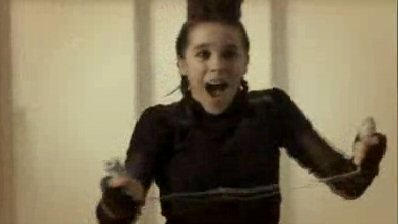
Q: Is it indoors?
A: Yes, it is indoors.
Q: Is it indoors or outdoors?
A: It is indoors.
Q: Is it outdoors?
A: No, it is indoors.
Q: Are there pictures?
A: No, there are no pictures.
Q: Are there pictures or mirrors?
A: No, there are no pictures or mirrors.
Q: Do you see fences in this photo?
A: No, there are no fences.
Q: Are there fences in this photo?
A: No, there are no fences.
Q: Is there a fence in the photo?
A: No, there are no fences.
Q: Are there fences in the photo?
A: No, there are no fences.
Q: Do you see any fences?
A: No, there are no fences.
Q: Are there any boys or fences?
A: No, there are no fences or boys.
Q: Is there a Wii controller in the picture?
A: Yes, there is a Wii controller.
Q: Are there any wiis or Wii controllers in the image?
A: Yes, there is a Wii controller.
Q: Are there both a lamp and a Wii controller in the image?
A: No, there is a Wii controller but no lamps.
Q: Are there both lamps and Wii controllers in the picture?
A: No, there is a Wii controller but no lamps.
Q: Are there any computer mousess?
A: No, there are no computer mousess.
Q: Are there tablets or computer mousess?
A: No, there are no computer mousess or tablets.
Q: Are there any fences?
A: No, there are no fences.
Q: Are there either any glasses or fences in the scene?
A: No, there are no fences or glasses.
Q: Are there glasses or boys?
A: No, there are no boys or glasses.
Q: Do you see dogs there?
A: No, there are no dogs.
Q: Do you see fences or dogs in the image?
A: No, there are no dogs or fences.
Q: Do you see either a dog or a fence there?
A: No, there are no dogs or fences.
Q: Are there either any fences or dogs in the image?
A: No, there are no dogs or fences.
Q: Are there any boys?
A: No, there are no boys.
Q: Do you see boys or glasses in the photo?
A: No, there are no boys or glasses.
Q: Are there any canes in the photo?
A: No, there are no canes.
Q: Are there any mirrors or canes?
A: No, there are no canes or mirrors.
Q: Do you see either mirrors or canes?
A: No, there are no canes or mirrors.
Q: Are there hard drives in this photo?
A: No, there are no hard drives.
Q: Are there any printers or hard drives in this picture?
A: No, there are no hard drives or printers.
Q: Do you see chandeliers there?
A: No, there are no chandeliers.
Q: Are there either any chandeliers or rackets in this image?
A: No, there are no chandeliers or rackets.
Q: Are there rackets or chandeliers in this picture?
A: No, there are no chandeliers or rackets.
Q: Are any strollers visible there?
A: No, there are no strollers.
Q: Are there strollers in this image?
A: No, there are no strollers.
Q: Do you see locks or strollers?
A: No, there are no strollers or locks.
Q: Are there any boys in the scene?
A: No, there are no boys.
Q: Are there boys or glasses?
A: No, there are no boys or glasses.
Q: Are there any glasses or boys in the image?
A: No, there are no boys or glasses.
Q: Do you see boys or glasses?
A: No, there are no boys or glasses.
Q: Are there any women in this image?
A: Yes, there is a woman.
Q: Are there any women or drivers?
A: Yes, there is a woman.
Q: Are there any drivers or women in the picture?
A: Yes, there is a woman.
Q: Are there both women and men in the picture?
A: No, there is a woman but no men.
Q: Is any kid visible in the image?
A: No, there are no children.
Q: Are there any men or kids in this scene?
A: No, there are no kids or men.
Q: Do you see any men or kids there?
A: No, there are no kids or men.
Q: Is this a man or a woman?
A: This is a woman.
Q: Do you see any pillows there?
A: No, there are no pillows.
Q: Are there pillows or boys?
A: No, there are no pillows or boys.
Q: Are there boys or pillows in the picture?
A: No, there are no pillows or boys.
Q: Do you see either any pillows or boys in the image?
A: No, there are no pillows or boys.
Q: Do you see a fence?
A: No, there are no fences.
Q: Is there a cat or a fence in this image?
A: No, there are no fences or cats.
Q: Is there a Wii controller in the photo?
A: Yes, there is a Wii controller.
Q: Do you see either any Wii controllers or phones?
A: Yes, there is a Wii controller.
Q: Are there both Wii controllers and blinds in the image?
A: No, there is a Wii controller but no blinds.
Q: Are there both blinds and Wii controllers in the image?
A: No, there is a Wii controller but no blinds.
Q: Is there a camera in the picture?
A: No, there are no cameras.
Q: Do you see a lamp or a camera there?
A: No, there are no cameras or lamps.